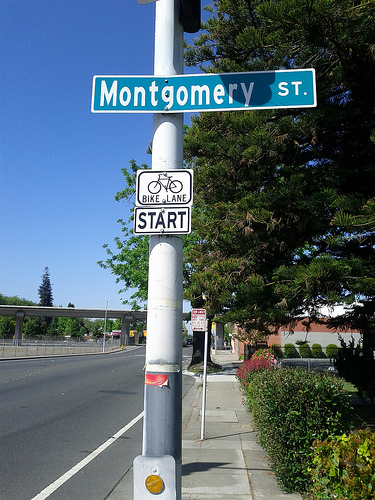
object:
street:
[4, 345, 15, 395]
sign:
[135, 168, 194, 205]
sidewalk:
[152, 365, 288, 497]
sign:
[134, 205, 194, 236]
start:
[135, 211, 185, 230]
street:
[109, 338, 143, 362]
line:
[83, 410, 143, 465]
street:
[107, 393, 118, 446]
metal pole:
[131, 0, 184, 500]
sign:
[190, 307, 207, 331]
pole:
[200, 331, 209, 441]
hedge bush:
[249, 366, 357, 492]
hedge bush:
[325, 342, 339, 356]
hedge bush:
[282, 343, 299, 357]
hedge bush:
[271, 342, 283, 357]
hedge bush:
[303, 427, 373, 499]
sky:
[2, 1, 90, 207]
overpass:
[20, 305, 117, 322]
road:
[16, 377, 96, 454]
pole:
[137, 0, 180, 493]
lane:
[50, 418, 110, 497]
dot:
[144, 474, 166, 496]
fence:
[0, 337, 121, 357]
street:
[128, 393, 141, 424]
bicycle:
[148, 171, 184, 194]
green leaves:
[195, 120, 306, 304]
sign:
[90, 68, 317, 113]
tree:
[114, 0, 372, 347]